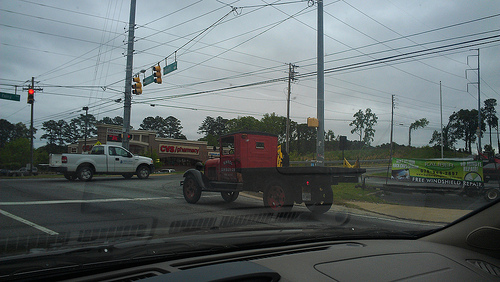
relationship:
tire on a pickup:
[77, 166, 94, 181] [48, 144, 155, 182]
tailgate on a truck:
[38, 158, 70, 176] [50, 143, 157, 179]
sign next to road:
[370, 148, 482, 194] [21, 185, 163, 220]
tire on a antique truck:
[74, 157, 99, 187] [180, 131, 367, 217]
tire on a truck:
[214, 185, 244, 206] [177, 132, 361, 217]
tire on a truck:
[307, 186, 337, 214] [172, 119, 372, 215]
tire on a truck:
[259, 183, 292, 215] [172, 119, 372, 215]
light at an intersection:
[26, 85, 33, 104] [0, 162, 201, 207]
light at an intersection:
[130, 72, 141, 93] [0, 162, 201, 207]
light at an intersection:
[150, 64, 162, 85] [0, 162, 201, 207]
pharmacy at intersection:
[57, 116, 217, 173] [45, 54, 360, 247]